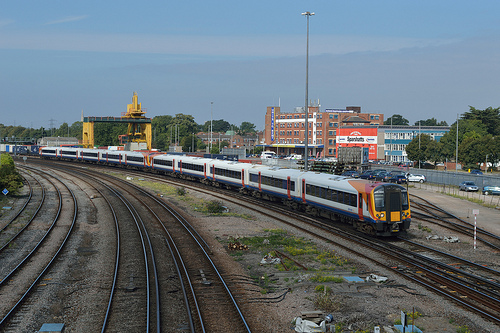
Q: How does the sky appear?
A: Blue with some clouds.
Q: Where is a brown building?
A: In the distance.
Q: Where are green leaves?
A: On many trees.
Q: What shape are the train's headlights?
A: Round.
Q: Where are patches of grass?
A: Between the tracks.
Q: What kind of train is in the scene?
A: A passenger train.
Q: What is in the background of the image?
A: Buildings.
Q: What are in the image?
A: Railway lines.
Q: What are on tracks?
A: Trains.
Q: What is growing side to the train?
A: Grass.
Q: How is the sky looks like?
A: Clear.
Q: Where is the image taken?
A: Downtown area.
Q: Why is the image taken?
A: Remembrance.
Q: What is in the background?
A: Trees.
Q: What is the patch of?
A: Grass.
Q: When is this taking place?
A: Daytime.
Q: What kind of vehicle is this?
A: Train.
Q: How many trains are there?
A: One.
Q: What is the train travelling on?
A: Train tracks.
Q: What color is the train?
A: Yellow, red and silver.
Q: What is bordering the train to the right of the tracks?
A: Dirt and grass.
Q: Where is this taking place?
A: On the train tracks.